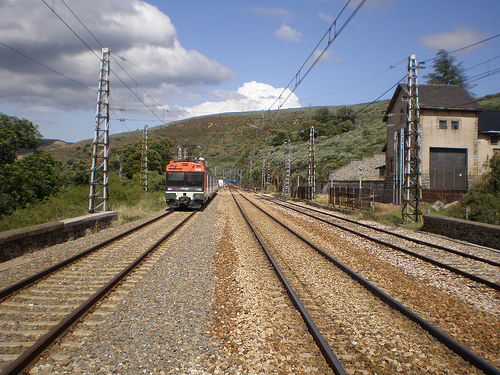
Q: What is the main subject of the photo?
A: Train.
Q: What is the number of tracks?
A: 3.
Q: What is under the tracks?
A: Gravel.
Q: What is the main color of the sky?
A: Blue.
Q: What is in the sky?
A: Clouds.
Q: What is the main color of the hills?
A: Green.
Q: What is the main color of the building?
A: Beige.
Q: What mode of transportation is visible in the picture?
A: Train.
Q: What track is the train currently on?
A: The left track.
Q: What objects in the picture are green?
A: Trees and grass.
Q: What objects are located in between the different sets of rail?
A: Gravel.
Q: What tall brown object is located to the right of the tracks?
A: A building.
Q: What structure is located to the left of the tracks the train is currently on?
A: A curb.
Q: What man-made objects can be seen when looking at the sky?
A: Wires.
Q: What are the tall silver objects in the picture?
A: Electrical towers.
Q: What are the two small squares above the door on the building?
A: Windows.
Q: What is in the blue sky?
A: White and grey clouds.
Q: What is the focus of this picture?
A: The Train.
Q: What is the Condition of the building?
A: Good.